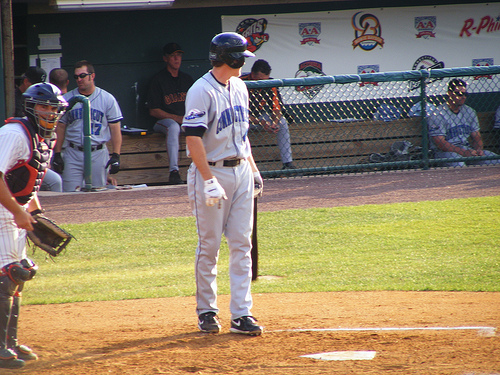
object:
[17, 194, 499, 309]
field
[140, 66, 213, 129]
shirt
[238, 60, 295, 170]
player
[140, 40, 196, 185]
player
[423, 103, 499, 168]
uniform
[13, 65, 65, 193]
man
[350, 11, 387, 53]
logo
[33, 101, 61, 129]
head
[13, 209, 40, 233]
hand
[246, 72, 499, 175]
fence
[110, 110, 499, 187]
bench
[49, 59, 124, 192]
man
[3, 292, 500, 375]
dirt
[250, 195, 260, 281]
bat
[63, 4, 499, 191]
dugout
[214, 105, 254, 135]
writing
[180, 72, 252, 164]
shirt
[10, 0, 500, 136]
wall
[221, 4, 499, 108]
banner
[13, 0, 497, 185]
home plate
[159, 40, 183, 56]
black hat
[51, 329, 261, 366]
batter's shadow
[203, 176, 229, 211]
baseball glove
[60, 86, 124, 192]
gray uniform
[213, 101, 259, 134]
blue writing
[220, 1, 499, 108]
white base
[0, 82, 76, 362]
behind hitter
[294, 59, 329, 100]
logo's on wall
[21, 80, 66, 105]
blue helmet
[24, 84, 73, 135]
safety equipment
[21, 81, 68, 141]
batting helmet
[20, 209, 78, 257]
catchers mitt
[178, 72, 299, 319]
baseball uniform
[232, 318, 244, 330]
white cleats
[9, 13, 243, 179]
rubber home plate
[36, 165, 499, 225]
dirt around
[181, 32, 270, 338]
baseball player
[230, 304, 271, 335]
standing on dirt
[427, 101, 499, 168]
gray uniform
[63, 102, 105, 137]
blue writing on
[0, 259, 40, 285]
black padding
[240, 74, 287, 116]
orange shirt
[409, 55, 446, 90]
banner on dugout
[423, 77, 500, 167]
baseball player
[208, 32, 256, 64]
helmet is black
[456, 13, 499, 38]
banner on the wall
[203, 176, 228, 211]
gloves are white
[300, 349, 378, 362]
diamond is in dirt